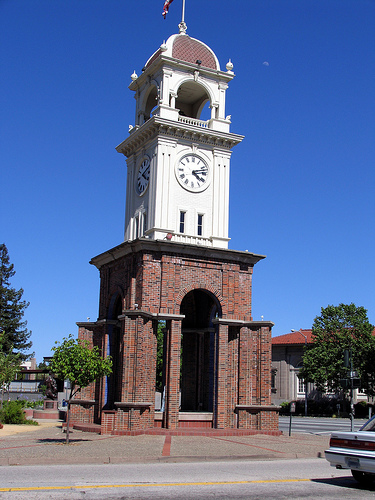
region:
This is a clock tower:
[42, 6, 312, 437]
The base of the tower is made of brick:
[66, 242, 290, 440]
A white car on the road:
[317, 412, 372, 478]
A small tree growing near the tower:
[42, 328, 121, 448]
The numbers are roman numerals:
[122, 151, 222, 196]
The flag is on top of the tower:
[159, 0, 198, 40]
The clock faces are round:
[118, 149, 220, 192]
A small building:
[274, 330, 366, 407]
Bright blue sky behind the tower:
[8, 10, 349, 289]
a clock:
[173, 150, 214, 192]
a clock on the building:
[180, 153, 210, 191]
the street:
[184, 457, 238, 475]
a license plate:
[346, 455, 361, 468]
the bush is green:
[64, 346, 94, 370]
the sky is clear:
[283, 173, 343, 242]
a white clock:
[177, 149, 212, 190]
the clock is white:
[171, 150, 214, 196]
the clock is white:
[181, 151, 215, 183]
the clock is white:
[164, 140, 214, 191]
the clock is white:
[182, 147, 217, 194]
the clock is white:
[173, 149, 218, 204]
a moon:
[254, 48, 278, 77]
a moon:
[257, 50, 277, 72]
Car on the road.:
[321, 410, 372, 490]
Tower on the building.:
[109, 0, 246, 248]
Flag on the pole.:
[156, 0, 187, 24]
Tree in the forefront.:
[38, 336, 116, 444]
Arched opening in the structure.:
[173, 277, 229, 432]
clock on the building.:
[171, 144, 213, 194]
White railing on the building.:
[174, 110, 212, 128]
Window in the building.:
[290, 368, 307, 398]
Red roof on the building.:
[272, 322, 373, 346]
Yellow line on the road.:
[0, 474, 349, 499]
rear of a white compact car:
[324, 411, 374, 488]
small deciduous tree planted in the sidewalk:
[45, 333, 113, 445]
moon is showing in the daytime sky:
[260, 59, 270, 68]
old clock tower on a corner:
[62, 1, 284, 436]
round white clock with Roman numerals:
[176, 153, 209, 189]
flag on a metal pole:
[158, 0, 187, 35]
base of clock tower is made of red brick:
[63, 3, 283, 435]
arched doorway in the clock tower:
[175, 284, 218, 418]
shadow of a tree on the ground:
[34, 436, 93, 445]